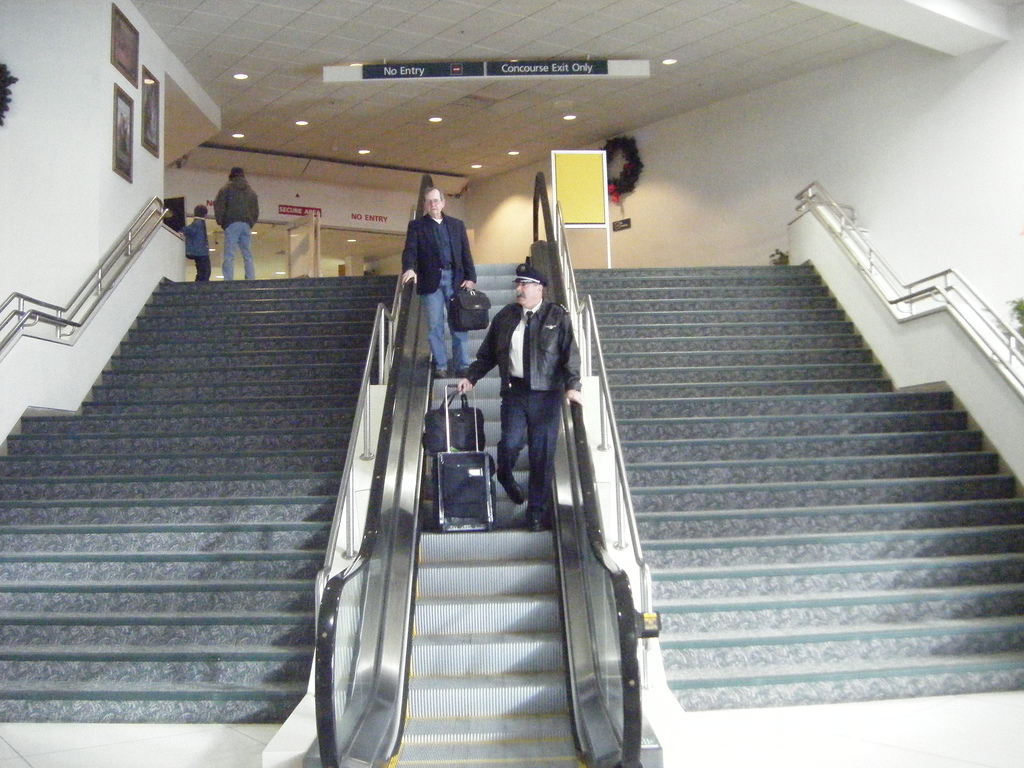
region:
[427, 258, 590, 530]
pilot going down the escalator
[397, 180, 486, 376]
man with glasses on the escalator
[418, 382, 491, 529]
luggage in the hand of the pilot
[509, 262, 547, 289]
black hat on the pilot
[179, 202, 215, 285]
a little boy at the top of the stairs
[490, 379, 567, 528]
black pants on the pilot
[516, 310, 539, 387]
a black tie on the pilot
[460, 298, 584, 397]
black jacket on the pilot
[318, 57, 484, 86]
Blue sign on the ceiling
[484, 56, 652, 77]
Blue sign on the ceiling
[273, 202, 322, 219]
Red sign on the wall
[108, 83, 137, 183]
Painting on the wall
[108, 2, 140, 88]
Painting on the wall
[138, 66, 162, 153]
Painting on the wall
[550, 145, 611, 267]
Yellow sign with white frame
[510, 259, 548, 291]
Man is wearing a black hat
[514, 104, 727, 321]
A yellow sign at the top of the stairs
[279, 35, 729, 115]
A black sign on the ceiling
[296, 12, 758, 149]
The black sign has white letters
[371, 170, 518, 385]
The man is wearing a blazer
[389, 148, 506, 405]
The man is holding a black bag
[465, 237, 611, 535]
The man is wearing a hat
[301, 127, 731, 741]
The people are riding the escalator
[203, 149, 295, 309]
The person is wearing a green coat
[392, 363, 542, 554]
The black bag is on the stair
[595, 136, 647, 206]
green and red holiday wreath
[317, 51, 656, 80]
long sign in white and blue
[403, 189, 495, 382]
man carying shoulder bag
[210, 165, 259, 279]
man wearing dark green jacket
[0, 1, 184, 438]
silver railing on wall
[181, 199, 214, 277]
child wearing blue coat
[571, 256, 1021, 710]
empty carpeted steps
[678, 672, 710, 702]
step on the stairs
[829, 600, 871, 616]
step on the stairs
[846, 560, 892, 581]
step on the stairs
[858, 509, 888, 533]
step on the stairs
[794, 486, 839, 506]
step on the stairs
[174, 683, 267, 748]
step on the stairs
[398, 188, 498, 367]
man wearing navy jacket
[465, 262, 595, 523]
man wearing black jacket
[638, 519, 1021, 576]
A step on a stairway.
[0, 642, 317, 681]
A step on a stairway.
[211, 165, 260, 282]
A person is standing up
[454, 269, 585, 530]
A person is standing up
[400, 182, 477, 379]
A person is standing up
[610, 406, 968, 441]
A step on a stairway.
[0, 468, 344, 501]
A step on a stairway.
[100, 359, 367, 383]
A step on a stairway.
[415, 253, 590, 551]
man holding two suitcases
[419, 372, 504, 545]
the suitcases are black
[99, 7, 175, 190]
three pictures on the wall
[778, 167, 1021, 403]
handrails on side the steps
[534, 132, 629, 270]
a sign color yellow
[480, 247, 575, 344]
man has a black cap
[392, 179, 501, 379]
man holding a black satchel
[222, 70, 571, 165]
lights on the ceiling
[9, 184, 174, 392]
handrails on the wall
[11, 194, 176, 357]
the handrails are metal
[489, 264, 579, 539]
A person is standing up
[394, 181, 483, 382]
A person is standing up